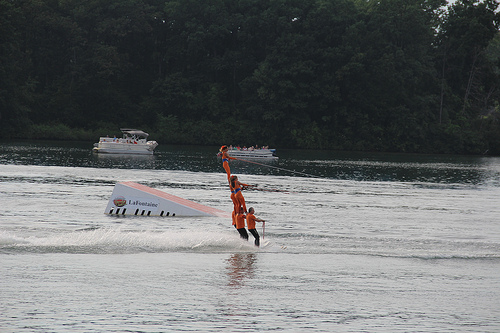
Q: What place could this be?
A: It is a lake.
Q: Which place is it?
A: It is a lake.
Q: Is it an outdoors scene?
A: Yes, it is outdoors.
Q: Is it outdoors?
A: Yes, it is outdoors.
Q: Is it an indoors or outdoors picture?
A: It is outdoors.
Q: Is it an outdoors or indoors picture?
A: It is outdoors.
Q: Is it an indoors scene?
A: No, it is outdoors.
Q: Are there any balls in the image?
A: No, there are no balls.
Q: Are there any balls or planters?
A: No, there are no balls or planters.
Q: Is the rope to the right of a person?
A: Yes, the rope is to the right of a person.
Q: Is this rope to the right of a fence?
A: No, the rope is to the right of a person.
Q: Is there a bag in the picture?
A: No, there are no bags.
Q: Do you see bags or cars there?
A: No, there are no bags or cars.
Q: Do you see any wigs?
A: No, there are no wigs.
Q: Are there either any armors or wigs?
A: No, there are no wigs or armors.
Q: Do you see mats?
A: No, there are no mats.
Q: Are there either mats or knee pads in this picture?
A: No, there are no mats or knee pads.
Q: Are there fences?
A: No, there are no fences.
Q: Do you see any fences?
A: No, there are no fences.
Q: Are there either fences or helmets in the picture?
A: No, there are no fences or helmets.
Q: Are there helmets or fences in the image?
A: No, there are no fences or helmets.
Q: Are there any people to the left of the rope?
A: Yes, there is a person to the left of the rope.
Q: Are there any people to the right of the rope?
A: No, the person is to the left of the rope.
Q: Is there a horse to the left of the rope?
A: No, there is a person to the left of the rope.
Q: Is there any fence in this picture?
A: No, there are no fences.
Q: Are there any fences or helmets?
A: No, there are no fences or helmets.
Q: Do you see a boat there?
A: Yes, there is a boat.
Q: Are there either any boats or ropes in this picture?
A: Yes, there is a boat.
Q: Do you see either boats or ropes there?
A: Yes, there is a boat.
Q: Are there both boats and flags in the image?
A: No, there is a boat but no flags.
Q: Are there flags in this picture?
A: No, there are no flags.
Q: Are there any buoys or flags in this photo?
A: No, there are no flags or buoys.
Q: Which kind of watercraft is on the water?
A: The watercraft is a boat.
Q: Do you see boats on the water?
A: Yes, there is a boat on the water.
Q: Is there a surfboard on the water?
A: No, there is a boat on the water.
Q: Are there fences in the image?
A: No, there are no fences.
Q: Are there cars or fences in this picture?
A: No, there are no fences or cars.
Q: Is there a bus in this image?
A: No, there are no buses.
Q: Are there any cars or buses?
A: No, there are no buses or cars.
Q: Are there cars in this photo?
A: No, there are no cars.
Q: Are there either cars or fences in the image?
A: No, there are no cars or fences.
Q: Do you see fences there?
A: No, there are no fences.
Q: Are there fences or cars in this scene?
A: No, there are no fences or cars.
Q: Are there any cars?
A: No, there are no cars.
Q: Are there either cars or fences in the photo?
A: No, there are no cars or fences.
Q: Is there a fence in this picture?
A: No, there are no fences.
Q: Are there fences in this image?
A: No, there are no fences.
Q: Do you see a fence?
A: No, there are no fences.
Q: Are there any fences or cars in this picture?
A: No, there are no fences or cars.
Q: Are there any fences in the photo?
A: No, there are no fences.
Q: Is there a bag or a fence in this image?
A: No, there are no fences or bags.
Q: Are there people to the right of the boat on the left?
A: Yes, there are people to the right of the boat.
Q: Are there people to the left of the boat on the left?
A: No, the people are to the right of the boat.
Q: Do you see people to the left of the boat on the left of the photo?
A: No, the people are to the right of the boat.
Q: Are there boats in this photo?
A: Yes, there is a boat.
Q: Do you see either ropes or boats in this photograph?
A: Yes, there is a boat.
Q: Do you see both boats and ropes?
A: Yes, there are both a boat and a rope.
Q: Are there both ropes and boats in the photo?
A: Yes, there are both a boat and a rope.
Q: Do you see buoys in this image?
A: No, there are no buoys.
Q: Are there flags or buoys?
A: No, there are no buoys or flags.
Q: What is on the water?
A: The boat is on the water.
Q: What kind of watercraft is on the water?
A: The watercraft is a boat.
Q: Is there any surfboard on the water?
A: No, there is a boat on the water.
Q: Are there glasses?
A: No, there are no glasses.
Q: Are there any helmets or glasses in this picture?
A: No, there are no glasses or helmets.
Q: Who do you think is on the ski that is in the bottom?
A: The man is on the ski.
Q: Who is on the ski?
A: The man is on the ski.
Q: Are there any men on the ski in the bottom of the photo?
A: Yes, there is a man on the ski.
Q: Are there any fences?
A: No, there are no fences.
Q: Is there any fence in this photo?
A: No, there are no fences.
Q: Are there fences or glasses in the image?
A: No, there are no fences or glasses.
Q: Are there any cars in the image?
A: No, there are no cars.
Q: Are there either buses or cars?
A: No, there are no cars or buses.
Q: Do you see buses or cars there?
A: No, there are no cars or buses.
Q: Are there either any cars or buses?
A: No, there are no cars or buses.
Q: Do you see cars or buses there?
A: No, there are no cars or buses.